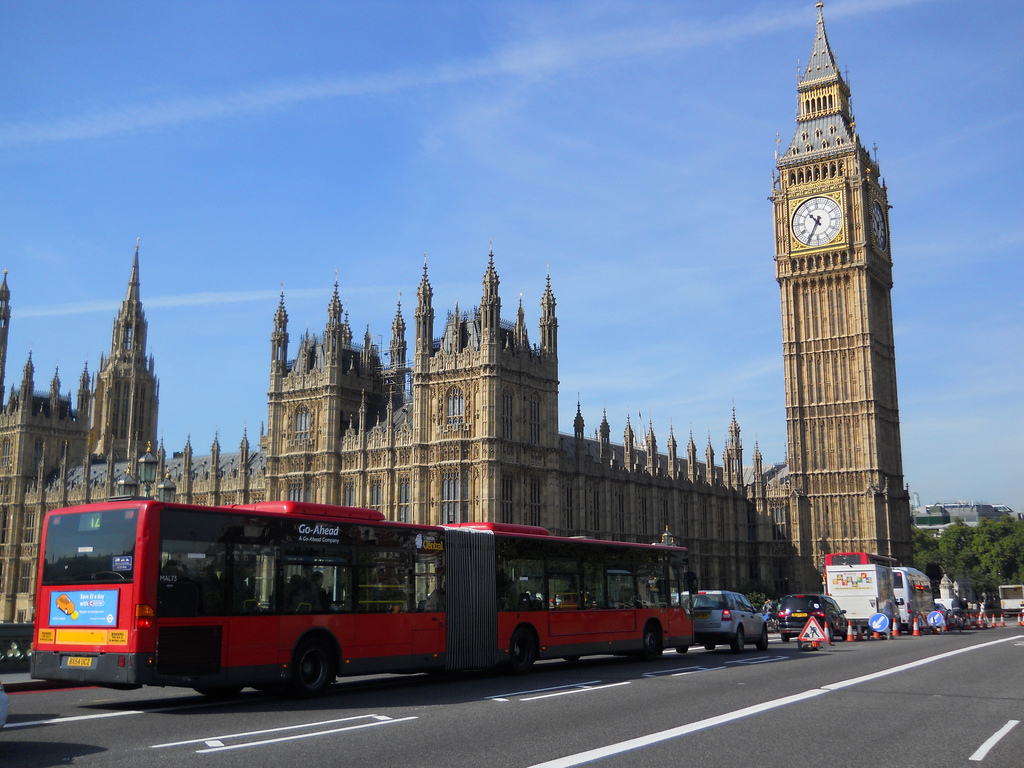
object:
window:
[503, 467, 516, 525]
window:
[503, 384, 514, 440]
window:
[399, 471, 412, 524]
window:
[369, 471, 385, 511]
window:
[288, 480, 312, 502]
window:
[641, 492, 647, 536]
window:
[662, 492, 668, 537]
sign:
[799, 616, 829, 647]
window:
[153, 506, 674, 619]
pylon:
[846, 620, 854, 642]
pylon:
[873, 632, 881, 640]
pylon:
[892, 617, 898, 635]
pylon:
[914, 618, 920, 636]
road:
[0, 621, 1024, 768]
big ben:
[774, 0, 905, 564]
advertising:
[47, 582, 121, 626]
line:
[531, 634, 1024, 768]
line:
[966, 718, 1020, 762]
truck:
[826, 552, 905, 625]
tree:
[915, 515, 1024, 610]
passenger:
[304, 572, 328, 615]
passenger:
[288, 573, 301, 613]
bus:
[28, 499, 694, 696]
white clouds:
[395, 48, 645, 213]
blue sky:
[0, 0, 1024, 514]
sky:
[235, 164, 303, 212]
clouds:
[0, 2, 1024, 510]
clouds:
[123, 80, 392, 164]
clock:
[791, 196, 845, 247]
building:
[0, 237, 789, 627]